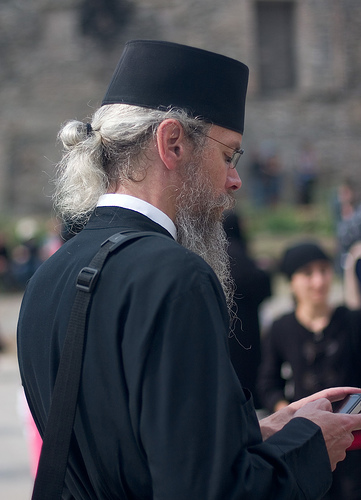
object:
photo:
[0, 0, 361, 500]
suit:
[17, 206, 330, 499]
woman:
[254, 243, 361, 411]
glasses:
[189, 127, 244, 169]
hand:
[294, 412, 361, 471]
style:
[55, 103, 162, 214]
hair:
[55, 103, 198, 223]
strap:
[31, 230, 147, 499]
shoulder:
[148, 246, 223, 340]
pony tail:
[60, 121, 106, 214]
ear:
[157, 120, 181, 170]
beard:
[175, 187, 232, 327]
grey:
[182, 216, 205, 250]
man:
[14, 38, 361, 500]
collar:
[96, 193, 177, 241]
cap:
[101, 41, 249, 134]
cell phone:
[334, 393, 361, 414]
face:
[197, 125, 243, 221]